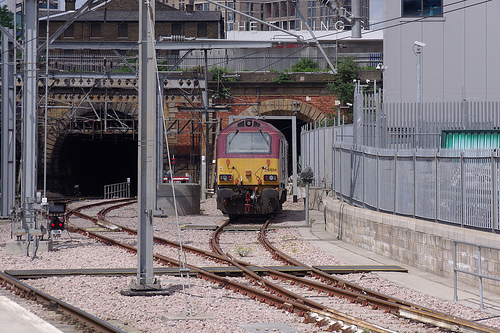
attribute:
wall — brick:
[221, 94, 339, 127]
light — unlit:
[262, 174, 276, 184]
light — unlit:
[215, 173, 237, 185]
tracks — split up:
[204, 209, 498, 331]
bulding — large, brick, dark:
[34, 1, 231, 43]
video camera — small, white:
[408, 37, 430, 55]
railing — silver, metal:
[34, 50, 336, 70]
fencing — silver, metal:
[294, 82, 489, 238]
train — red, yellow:
[209, 110, 293, 218]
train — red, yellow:
[181, 101, 310, 245]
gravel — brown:
[0, 195, 498, 332]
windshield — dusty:
[225, 130, 271, 154]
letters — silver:
[219, 16, 351, 37]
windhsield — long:
[217, 121, 281, 159]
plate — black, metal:
[218, 192, 282, 213]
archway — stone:
[48, 104, 145, 181]